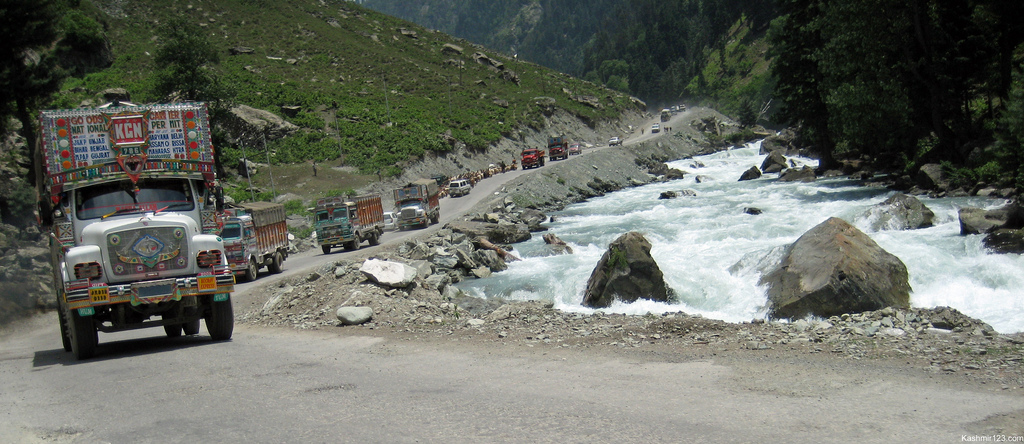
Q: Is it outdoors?
A: Yes, it is outdoors.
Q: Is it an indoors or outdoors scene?
A: It is outdoors.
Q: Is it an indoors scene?
A: No, it is outdoors.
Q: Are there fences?
A: No, there are no fences.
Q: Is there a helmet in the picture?
A: No, there are no helmets.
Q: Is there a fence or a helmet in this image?
A: No, there are no helmets or fences.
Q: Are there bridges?
A: No, there are no bridges.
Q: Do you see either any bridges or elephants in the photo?
A: No, there are no bridges or elephants.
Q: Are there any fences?
A: No, there are no fences.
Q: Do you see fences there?
A: No, there are no fences.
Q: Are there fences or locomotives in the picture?
A: No, there are no fences or locomotives.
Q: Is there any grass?
A: Yes, there is grass.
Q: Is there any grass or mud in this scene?
A: Yes, there is grass.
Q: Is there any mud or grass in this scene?
A: Yes, there is grass.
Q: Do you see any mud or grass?
A: Yes, there is grass.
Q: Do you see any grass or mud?
A: Yes, there is grass.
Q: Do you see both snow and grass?
A: No, there is grass but no snow.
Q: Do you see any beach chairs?
A: No, there are no beach chairs.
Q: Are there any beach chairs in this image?
A: No, there are no beach chairs.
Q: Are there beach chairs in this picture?
A: No, there are no beach chairs.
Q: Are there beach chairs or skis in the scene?
A: No, there are no beach chairs or skis.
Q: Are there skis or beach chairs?
A: No, there are no beach chairs or skis.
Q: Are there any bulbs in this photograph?
A: No, there are no bulbs.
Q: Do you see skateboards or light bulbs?
A: No, there are no light bulbs or skateboards.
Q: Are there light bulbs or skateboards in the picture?
A: No, there are no light bulbs or skateboards.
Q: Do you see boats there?
A: No, there are no boats.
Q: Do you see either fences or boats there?
A: No, there are no boats or fences.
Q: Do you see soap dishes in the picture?
A: No, there are no soap dishes.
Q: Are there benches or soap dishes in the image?
A: No, there are no soap dishes or benches.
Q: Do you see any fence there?
A: No, there are no fences.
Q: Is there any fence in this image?
A: No, there are no fences.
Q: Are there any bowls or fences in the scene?
A: No, there are no fences or bowls.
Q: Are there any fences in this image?
A: No, there are no fences.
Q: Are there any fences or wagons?
A: No, there are no fences or wagons.